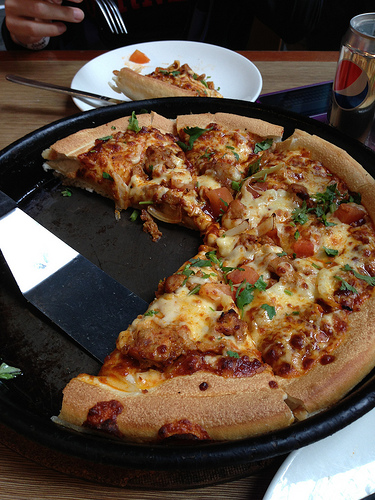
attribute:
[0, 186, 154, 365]
spatula — metal, silver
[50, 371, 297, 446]
crust — brown, spotted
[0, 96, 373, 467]
pan — black, brown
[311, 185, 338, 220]
basil — green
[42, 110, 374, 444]
pizza — sliced, cooked, cut, pictured, big, spicy, yellow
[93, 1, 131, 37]
fork — silver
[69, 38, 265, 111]
plate — white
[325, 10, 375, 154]
can — silver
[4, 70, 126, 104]
knife — pictured, shiny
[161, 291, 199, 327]
cheese — brown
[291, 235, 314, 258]
tomatoe — red